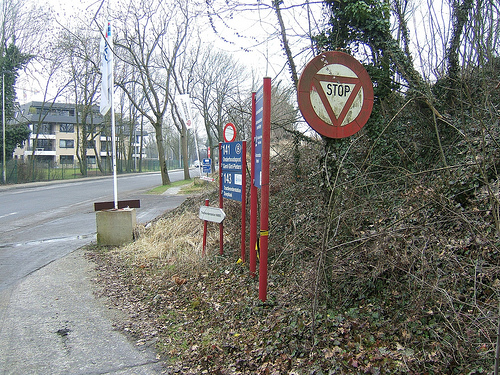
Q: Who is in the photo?
A: No one.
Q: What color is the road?
A: Black.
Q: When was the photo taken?
A: Afternoon.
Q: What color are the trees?
A: Green.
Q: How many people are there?
A: None.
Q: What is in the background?
A: Building.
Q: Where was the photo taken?
A: At a stop sign.